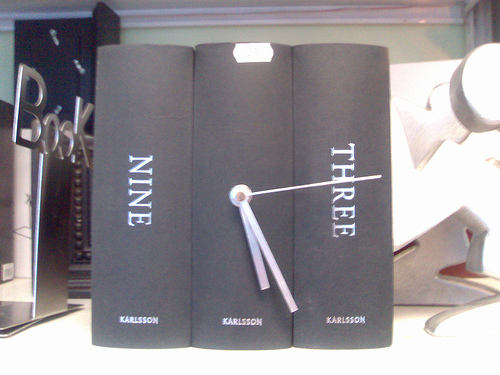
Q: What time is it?
A: Five twenty-five.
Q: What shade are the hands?
A: Silver.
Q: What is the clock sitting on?
A: Desk.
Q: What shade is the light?
A: Bright.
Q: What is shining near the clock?
A: Sunlight.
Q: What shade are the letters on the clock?
A: White.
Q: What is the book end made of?
A: Metal.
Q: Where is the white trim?
A: On the wall.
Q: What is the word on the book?
A: Nine.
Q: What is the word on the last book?
A: Three.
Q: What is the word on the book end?
A: Book.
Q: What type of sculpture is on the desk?
A: A book clock.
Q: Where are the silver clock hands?
A: On the book.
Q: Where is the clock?
A: Disguised as a book.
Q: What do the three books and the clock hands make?
A: A clock sculpture.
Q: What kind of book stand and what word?
A: Silver and book.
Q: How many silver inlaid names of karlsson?
A: Three.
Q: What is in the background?
A: Black cabinet.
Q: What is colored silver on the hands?
A: Minute hand.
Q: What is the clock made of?
A: Books.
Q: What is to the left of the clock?
A: A silver book holder.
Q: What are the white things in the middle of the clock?
A: The hands of the clock.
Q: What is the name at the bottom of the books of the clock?
A: Karlsson.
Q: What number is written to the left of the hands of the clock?
A: Nine.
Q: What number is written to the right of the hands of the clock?
A: Three.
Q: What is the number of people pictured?
A: Zero.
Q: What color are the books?
A: Black.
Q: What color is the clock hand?
A: White.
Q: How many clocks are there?
A: One.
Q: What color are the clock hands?
A: Silver.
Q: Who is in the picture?
A: There are no people.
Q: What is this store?
A: Brookstone.